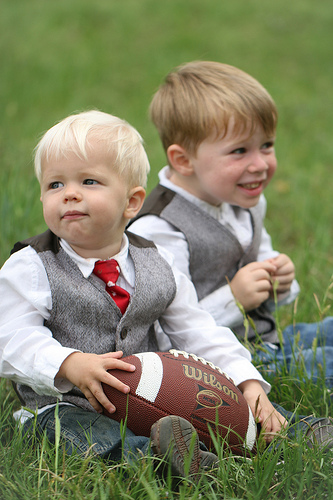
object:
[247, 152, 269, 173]
nose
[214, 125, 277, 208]
face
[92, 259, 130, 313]
red tie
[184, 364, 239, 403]
wilson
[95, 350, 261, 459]
football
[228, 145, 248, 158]
eyes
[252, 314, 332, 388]
blue jeans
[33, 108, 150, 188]
hair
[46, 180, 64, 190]
eyes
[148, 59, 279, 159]
red hair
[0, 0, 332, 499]
grass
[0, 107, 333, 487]
boy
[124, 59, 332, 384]
boy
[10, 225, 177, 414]
vests